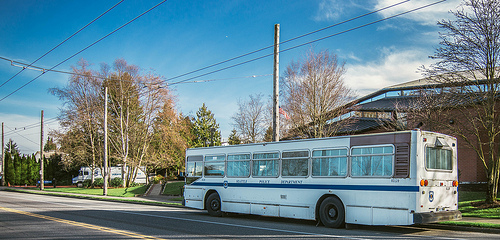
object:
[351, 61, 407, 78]
clouds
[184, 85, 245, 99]
sky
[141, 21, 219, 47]
clouds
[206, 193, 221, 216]
wheels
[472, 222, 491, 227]
grass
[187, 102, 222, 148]
tree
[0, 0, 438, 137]
power lines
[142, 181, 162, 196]
walkway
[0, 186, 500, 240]
road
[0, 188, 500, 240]
street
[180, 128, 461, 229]
bus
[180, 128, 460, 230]
passenger bus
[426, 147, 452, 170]
window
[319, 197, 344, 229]
tire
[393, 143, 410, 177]
vents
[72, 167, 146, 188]
box truck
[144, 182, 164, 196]
sidewalk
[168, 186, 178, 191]
grass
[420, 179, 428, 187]
tail light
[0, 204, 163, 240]
line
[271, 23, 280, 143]
pole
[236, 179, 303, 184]
lettering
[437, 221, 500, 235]
curb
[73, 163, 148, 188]
truck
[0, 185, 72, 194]
driveway